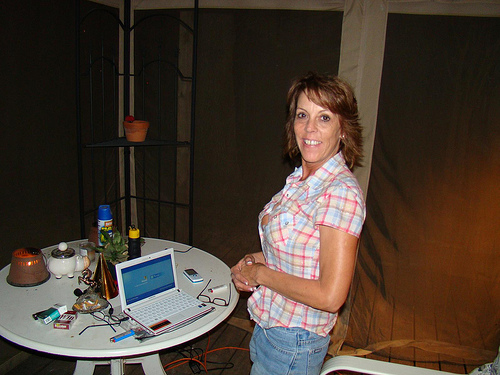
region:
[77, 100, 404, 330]
woman standing at table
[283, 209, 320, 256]
plaid pattern on shirt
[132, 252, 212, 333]
laptop on the table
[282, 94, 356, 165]
face of the woman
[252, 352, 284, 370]
jeans on the woman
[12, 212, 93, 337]
items on the table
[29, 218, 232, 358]
the table is round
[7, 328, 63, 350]
the table is white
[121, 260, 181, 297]
screen of the laptop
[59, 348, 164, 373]
legs of the chair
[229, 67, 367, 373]
Woman with brown hair wearing shirt and jeans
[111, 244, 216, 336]
white computer laptop on a round white table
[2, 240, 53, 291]
bug repellent candle on a white table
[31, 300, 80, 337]
cigarette packages on a white table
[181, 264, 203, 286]
small cellphone on a white table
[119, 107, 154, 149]
clay pot on a black shelf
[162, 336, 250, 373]
electrical cords on a floor space area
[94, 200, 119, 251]
aerosol can with blue top on a table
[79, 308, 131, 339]
reading glasses on a white table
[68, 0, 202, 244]
black wire stand with clay pot on shelf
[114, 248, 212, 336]
an open white netbook computer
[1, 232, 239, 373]
a small white table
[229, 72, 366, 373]
a woman standing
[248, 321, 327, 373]
a pair of blue jeans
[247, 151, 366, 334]
a red and blue striped shirt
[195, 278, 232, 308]
a pair of eyeglasses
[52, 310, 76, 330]
a pack of cigarettes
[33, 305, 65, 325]
a pack of cigarettes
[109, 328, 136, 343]
a blue cigarette lighter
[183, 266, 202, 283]
a candy bar style cell phone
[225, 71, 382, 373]
A woman standing up smiling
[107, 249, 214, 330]
A white laptop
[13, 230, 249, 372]
A round white table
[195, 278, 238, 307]
A black frame pair of glasses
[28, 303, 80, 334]
Boxes of cigarettes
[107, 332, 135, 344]
A light blue lighter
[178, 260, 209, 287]
A white cellphone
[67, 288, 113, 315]
Cigarette butts in an ashtray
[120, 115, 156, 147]
A brown flower pot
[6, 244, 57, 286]
A candle in a candle holder, lit up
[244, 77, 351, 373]
a lady standing in front of a table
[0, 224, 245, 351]
a white table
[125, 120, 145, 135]
a pot on a shelf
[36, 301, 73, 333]
packs of cigarettes on the table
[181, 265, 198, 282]
a cell phone on the table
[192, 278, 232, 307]
black glasses on the table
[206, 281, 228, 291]
a white lighter on the table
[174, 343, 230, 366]
cords under the table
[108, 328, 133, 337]
a blue lighter on the table